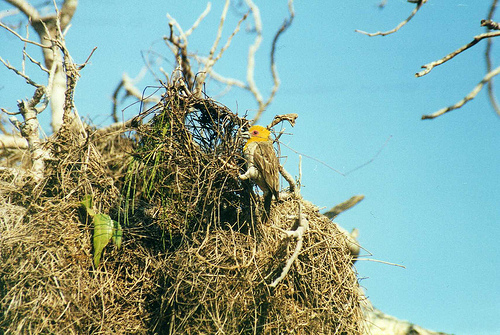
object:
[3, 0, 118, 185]
wood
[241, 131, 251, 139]
beak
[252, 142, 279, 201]
feathers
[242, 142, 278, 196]
body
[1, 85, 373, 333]
grass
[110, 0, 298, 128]
tree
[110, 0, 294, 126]
branches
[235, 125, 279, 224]
bird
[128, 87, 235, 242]
bench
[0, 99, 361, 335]
nest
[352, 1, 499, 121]
tree branches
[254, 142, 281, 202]
wing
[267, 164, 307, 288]
branch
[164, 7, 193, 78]
branch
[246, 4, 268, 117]
branch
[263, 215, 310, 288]
wood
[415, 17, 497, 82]
wood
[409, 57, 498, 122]
wood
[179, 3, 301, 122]
wood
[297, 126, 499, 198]
sky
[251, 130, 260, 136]
eye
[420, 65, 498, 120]
branch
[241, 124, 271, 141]
head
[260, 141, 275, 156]
feather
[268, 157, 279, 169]
feather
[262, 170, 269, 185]
feather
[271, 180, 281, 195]
feather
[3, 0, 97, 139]
tree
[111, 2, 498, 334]
trees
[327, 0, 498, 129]
wood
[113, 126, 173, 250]
green grass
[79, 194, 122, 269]
leaf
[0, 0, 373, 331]
tree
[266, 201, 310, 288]
stick branch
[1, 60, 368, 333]
weed grass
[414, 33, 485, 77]
branch